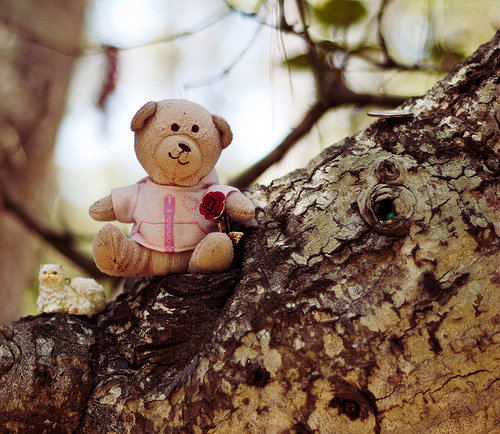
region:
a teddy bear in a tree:
[95, 100, 260, 275]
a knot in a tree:
[370, 186, 412, 226]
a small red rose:
[196, 190, 226, 219]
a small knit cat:
[37, 262, 107, 317]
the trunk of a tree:
[0, 14, 499, 432]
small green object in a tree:
[385, 209, 393, 217]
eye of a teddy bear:
[190, 124, 198, 132]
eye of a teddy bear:
[170, 123, 180, 133]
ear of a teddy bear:
[130, 103, 154, 131]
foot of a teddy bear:
[93, 227, 128, 270]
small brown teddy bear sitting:
[104, 89, 244, 289]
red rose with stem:
[191, 186, 233, 226]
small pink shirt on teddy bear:
[102, 173, 236, 258]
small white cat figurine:
[30, 261, 105, 323]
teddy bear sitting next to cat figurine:
[31, 85, 243, 326]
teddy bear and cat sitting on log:
[0, 82, 295, 390]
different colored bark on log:
[290, 168, 430, 343]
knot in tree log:
[355, 158, 420, 239]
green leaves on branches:
[274, 1, 381, 99]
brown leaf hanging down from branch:
[70, 32, 151, 130]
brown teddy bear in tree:
[118, 104, 244, 269]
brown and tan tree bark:
[15, 335, 88, 405]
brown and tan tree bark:
[120, 342, 177, 394]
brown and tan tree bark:
[197, 349, 251, 401]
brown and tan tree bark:
[251, 359, 292, 404]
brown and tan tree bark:
[319, 371, 384, 416]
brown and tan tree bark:
[375, 356, 447, 431]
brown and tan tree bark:
[393, 268, 450, 340]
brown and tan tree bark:
[321, 198, 367, 259]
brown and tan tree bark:
[411, 154, 453, 229]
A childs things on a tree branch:
[26, 82, 343, 345]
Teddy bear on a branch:
[96, 102, 291, 314]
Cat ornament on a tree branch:
[21, 231, 111, 327]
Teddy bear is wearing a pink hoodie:
[104, 124, 242, 304]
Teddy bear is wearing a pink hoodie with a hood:
[115, 99, 244, 270]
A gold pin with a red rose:
[199, 184, 254, 269]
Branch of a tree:
[293, 116, 464, 402]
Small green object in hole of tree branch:
[376, 192, 411, 240]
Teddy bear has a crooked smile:
[151, 131, 235, 173]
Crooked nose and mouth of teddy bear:
[148, 119, 213, 176]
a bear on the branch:
[84, 89, 261, 293]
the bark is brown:
[5, 25, 492, 416]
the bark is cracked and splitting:
[2, 80, 477, 430]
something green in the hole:
[380, 202, 400, 224]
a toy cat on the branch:
[32, 263, 109, 326]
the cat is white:
[33, 259, 105, 320]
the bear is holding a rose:
[86, 94, 252, 281]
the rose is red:
[194, 186, 229, 225]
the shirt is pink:
[104, 174, 239, 259]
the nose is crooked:
[149, 127, 213, 179]